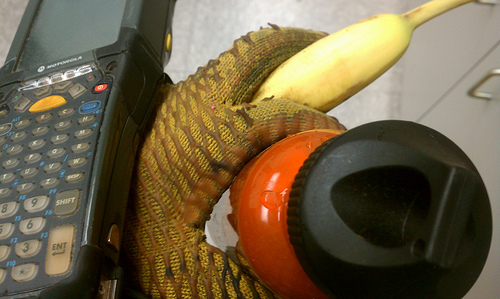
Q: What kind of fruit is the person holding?
A: A banana.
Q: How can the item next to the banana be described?
A: An orange and black container.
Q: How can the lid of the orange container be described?
A: A black removable lid with a finger hole at the top.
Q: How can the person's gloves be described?
A: They are tan.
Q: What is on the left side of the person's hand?
A: A black scanner.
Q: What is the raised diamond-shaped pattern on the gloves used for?
A: To have a better grip.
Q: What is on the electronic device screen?
A: Nothing.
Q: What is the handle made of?
A: Metal.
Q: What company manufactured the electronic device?
A: Motorola?.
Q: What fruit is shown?
A: Banana.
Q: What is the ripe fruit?
A: Banana.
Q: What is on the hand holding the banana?
A: Glove.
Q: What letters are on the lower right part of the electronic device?
A: ENT.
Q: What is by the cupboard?
A: A banana.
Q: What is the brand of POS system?
A: Motorola.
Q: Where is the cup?
A: In the mesh bag.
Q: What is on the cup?
A: A black lid.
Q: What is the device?
A: A black POS system.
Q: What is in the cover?
A: A banana and a cup.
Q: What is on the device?
A: Buttons and a screen.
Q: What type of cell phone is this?
A: Motorola.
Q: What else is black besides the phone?
A: A bottle lid.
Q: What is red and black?
A: A water bottle.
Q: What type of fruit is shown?
A: A banana.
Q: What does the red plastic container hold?
A: Water.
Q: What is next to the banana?
A: A drink thermos.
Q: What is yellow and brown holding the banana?
A: A glove.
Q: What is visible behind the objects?
A: The floor.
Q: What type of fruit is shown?
A: Banana.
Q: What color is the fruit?
A: Yellow.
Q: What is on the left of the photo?
A: Price scanner.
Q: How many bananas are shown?
A: One.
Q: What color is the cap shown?
A: Black.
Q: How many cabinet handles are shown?
A: Two.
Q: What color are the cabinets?
A: Silver.